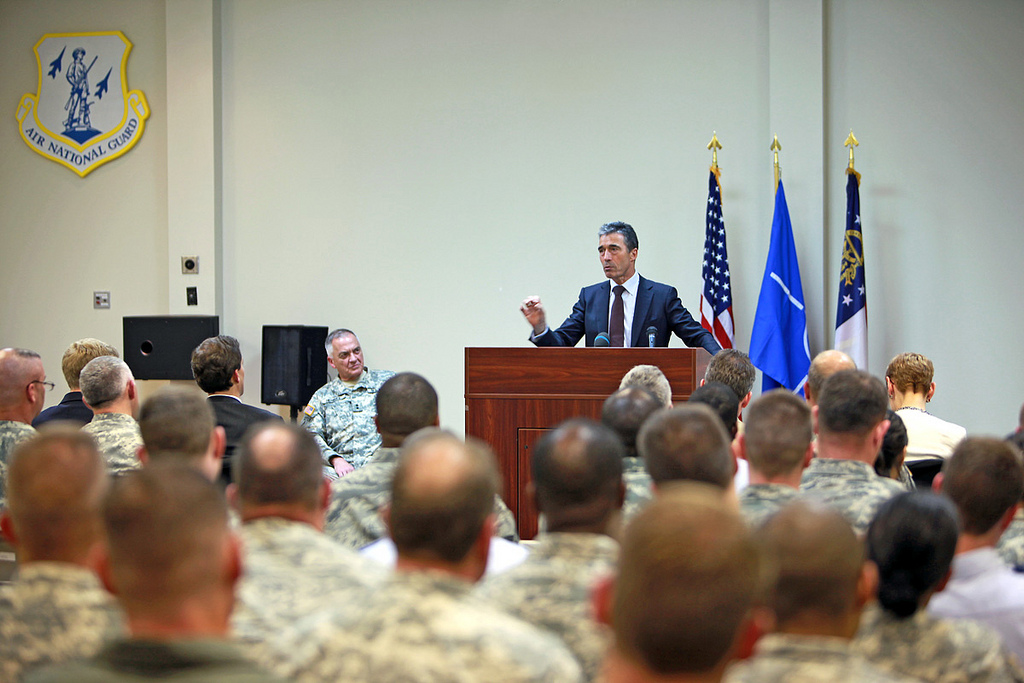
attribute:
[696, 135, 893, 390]
flags — american, grouped, different, blue, casting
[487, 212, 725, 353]
man — dressed, speaking, gesturing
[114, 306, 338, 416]
speakers — square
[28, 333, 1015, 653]
people — listening, uniformed, looking, bald, bespectacled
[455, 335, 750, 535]
podium — wooden